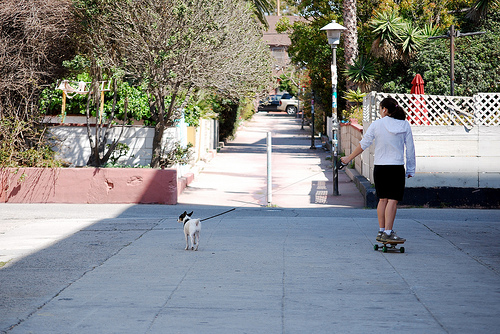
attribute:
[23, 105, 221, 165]
building — white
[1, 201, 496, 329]
ground — cement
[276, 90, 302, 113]
car — sedan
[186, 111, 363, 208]
walkway — concrete, large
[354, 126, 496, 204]
wall — short, red, concrete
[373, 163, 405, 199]
shorts — black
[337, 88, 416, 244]
person — young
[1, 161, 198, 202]
brick — red